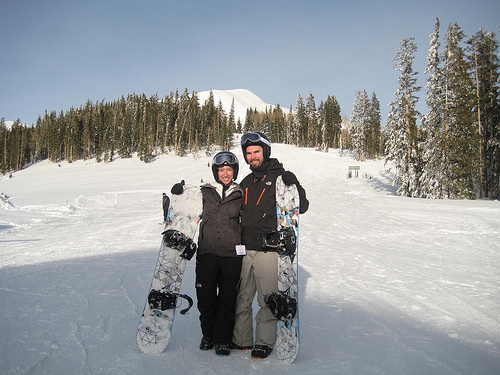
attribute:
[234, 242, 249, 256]
tag — white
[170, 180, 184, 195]
glove — black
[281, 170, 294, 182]
glove — black